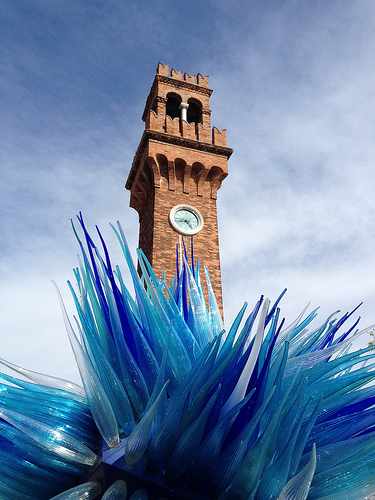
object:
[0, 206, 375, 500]
blue flower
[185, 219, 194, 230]
hand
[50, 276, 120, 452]
petal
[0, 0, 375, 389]
sky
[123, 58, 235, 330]
clock tower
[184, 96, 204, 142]
arch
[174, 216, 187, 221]
hand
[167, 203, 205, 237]
clock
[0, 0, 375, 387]
clouds